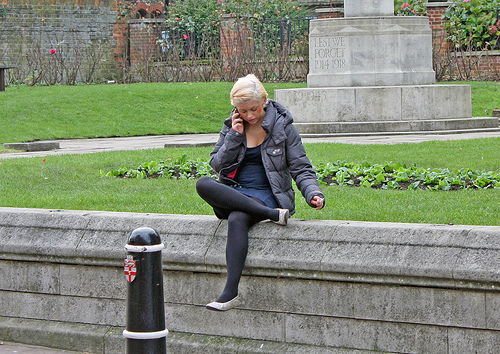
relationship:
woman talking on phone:
[198, 75, 327, 316] [233, 108, 241, 117]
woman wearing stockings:
[195, 71, 327, 311] [196, 170, 267, 294]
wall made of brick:
[1, 1, 498, 88] [112, 23, 119, 27]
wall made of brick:
[1, 1, 498, 88] [113, 29, 118, 31]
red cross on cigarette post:
[123, 260, 135, 280] [121, 225, 167, 352]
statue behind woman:
[250, 1, 467, 122] [179, 60, 339, 318]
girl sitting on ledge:
[193, 73, 326, 311] [6, 203, 484, 289]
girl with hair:
[193, 73, 326, 311] [228, 70, 268, 110]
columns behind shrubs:
[118, 20, 145, 75] [157, 3, 498, 87]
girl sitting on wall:
[193, 73, 326, 311] [3, 209, 497, 352]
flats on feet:
[178, 283, 280, 330] [203, 289, 244, 314]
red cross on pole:
[123, 260, 135, 280] [121, 222, 168, 352]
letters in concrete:
[306, 37, 349, 77] [364, 30, 434, 90]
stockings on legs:
[193, 176, 285, 312] [191, 172, 296, 319]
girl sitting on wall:
[122, 90, 369, 317] [226, 37, 447, 127]